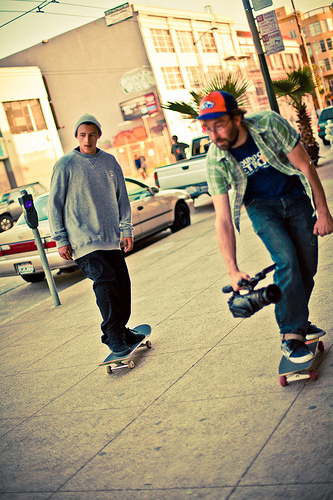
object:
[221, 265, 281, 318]
camera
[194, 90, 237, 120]
cap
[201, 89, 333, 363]
man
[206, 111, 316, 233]
squared shirt.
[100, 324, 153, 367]
skateboard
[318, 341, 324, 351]
wheels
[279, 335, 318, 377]
skateboard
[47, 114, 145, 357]
man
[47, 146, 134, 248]
grey top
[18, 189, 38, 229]
parking meter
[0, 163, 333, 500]
sidewalk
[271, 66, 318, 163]
palm tree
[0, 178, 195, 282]
car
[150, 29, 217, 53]
windows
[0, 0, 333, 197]
building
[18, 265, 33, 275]
license plate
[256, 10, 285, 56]
sign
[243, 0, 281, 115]
pole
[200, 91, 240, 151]
head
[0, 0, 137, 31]
power lines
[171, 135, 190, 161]
person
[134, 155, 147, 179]
person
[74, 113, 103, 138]
beanie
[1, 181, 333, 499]
title shaped blocks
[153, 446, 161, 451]
stain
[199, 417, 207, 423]
stain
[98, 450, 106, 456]
stain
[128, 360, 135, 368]
wheel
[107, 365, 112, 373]
wheel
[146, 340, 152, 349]
wheel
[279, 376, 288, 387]
wheel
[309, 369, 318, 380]
wheel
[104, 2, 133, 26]
sign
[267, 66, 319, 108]
palm leaves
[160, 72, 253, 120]
palm leaves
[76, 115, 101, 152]
guy's head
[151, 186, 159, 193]
mirror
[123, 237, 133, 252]
hand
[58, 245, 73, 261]
hand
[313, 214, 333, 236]
hand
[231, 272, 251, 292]
hand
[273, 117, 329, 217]
arm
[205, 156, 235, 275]
arm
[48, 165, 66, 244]
arm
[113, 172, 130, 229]
arm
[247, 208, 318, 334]
legs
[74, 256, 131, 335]
legs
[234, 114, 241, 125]
ear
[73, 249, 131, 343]
pants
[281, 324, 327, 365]
feet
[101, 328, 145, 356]
feet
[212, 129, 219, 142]
nose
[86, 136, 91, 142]
nose